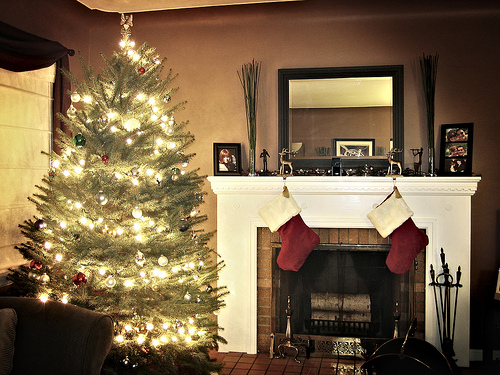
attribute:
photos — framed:
[433, 115, 475, 179]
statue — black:
[255, 145, 272, 175]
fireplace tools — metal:
[427, 247, 461, 365]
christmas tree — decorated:
[36, 14, 226, 358]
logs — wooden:
[296, 295, 383, 328]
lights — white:
[51, 153, 170, 195]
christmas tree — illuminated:
[21, 10, 230, 366]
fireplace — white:
[206, 170, 481, 367]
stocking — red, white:
[260, 187, 317, 271]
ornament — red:
[62, 267, 88, 287]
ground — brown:
[360, 50, 400, 90]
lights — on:
[136, 96, 186, 151]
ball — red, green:
[159, 253, 169, 272]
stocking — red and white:
[255, 190, 325, 268]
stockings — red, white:
[254, 192, 323, 267]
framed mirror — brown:
[267, 58, 409, 173]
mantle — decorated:
[207, 131, 498, 269]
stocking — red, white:
[249, 182, 335, 283]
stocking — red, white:
[347, 179, 466, 292]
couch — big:
[0, 296, 150, 367]